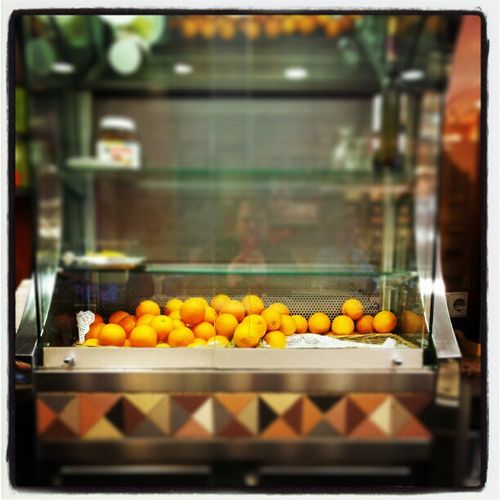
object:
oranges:
[371, 308, 400, 335]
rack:
[49, 5, 411, 306]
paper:
[76, 312, 415, 350]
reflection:
[182, 178, 299, 299]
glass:
[10, 10, 483, 362]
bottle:
[94, 113, 144, 169]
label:
[95, 139, 143, 170]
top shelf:
[62, 161, 414, 191]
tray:
[41, 312, 424, 369]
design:
[33, 390, 435, 442]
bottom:
[31, 366, 437, 464]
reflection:
[84, 12, 372, 85]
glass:
[52, 8, 391, 97]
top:
[10, 8, 478, 102]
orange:
[179, 295, 207, 326]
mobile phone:
[240, 238, 263, 274]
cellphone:
[241, 230, 263, 274]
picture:
[7, 9, 486, 495]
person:
[303, 206, 377, 284]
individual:
[193, 190, 302, 292]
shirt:
[308, 247, 373, 292]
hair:
[319, 199, 361, 243]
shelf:
[65, 165, 409, 194]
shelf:
[35, 263, 427, 389]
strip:
[38, 391, 432, 439]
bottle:
[346, 136, 371, 170]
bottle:
[329, 126, 358, 171]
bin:
[43, 276, 424, 350]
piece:
[42, 342, 426, 370]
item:
[41, 347, 423, 370]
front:
[32, 365, 437, 466]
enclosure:
[52, 286, 421, 347]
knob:
[452, 297, 466, 313]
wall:
[432, 17, 491, 363]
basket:
[45, 289, 421, 349]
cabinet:
[0, 0, 500, 500]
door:
[49, 439, 431, 496]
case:
[3, 10, 487, 494]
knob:
[390, 356, 407, 367]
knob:
[61, 356, 73, 366]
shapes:
[29, 391, 432, 444]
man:
[182, 182, 305, 292]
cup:
[236, 237, 259, 286]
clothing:
[190, 241, 307, 296]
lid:
[97, 113, 139, 132]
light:
[280, 61, 313, 86]